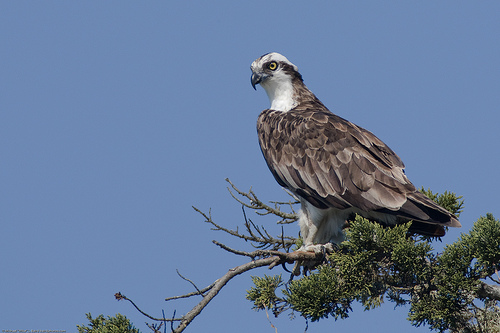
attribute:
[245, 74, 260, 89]
beak — curved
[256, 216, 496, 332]
needles — green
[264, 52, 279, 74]
eye — round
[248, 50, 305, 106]
head — white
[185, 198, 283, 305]
branch — light grey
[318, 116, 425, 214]
wing — bird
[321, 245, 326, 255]
claw — black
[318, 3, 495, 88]
sky — blue, daytime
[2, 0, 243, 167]
sky — blue, daytime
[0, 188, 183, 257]
sky — blue, daytime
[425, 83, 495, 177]
sky — blue, daytime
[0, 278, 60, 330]
sky — blue, daytime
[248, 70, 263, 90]
beak — black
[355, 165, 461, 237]
tail — grey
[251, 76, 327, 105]
neck — white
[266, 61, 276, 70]
eye — yellow, glowing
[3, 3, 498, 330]
sky — blue, clear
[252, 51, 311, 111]
head — white, black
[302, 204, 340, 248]
legs — white